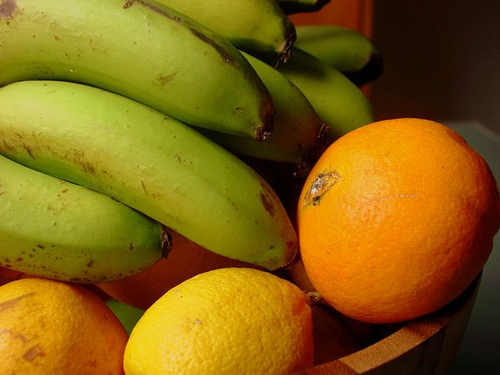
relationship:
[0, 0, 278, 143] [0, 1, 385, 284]
banana in bunch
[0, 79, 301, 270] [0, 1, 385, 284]
banana in bunch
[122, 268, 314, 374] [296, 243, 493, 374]
lemon in bowl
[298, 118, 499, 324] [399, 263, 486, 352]
orange resting on edge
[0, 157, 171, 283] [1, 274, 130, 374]
banana resting on orange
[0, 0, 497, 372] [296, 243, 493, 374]
fruit in bowl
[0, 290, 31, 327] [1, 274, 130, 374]
mark on orange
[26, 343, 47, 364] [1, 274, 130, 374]
mark on orange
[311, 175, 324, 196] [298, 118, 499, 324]
spot on orange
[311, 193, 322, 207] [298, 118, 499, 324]
spot on orange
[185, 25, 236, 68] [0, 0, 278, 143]
discoloration on banana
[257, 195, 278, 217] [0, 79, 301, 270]
discoloration on banana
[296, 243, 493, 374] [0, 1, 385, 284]
bowl holding bananas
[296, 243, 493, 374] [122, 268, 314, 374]
bowl holding lemon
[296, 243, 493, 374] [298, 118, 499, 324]
bowl holding orange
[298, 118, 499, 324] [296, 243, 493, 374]
orange in basket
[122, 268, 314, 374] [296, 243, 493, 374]
lemon in basket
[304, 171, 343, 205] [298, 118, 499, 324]
bruise on orange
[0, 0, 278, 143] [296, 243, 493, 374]
banana in basket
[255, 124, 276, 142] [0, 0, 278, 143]
stem on banana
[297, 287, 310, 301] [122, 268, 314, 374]
stem on lemon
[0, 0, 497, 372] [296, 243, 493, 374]
fruit in basket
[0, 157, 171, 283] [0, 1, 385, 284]
banana in bunch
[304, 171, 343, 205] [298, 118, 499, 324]
scar on orange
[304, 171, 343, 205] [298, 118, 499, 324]
spiderweb on orange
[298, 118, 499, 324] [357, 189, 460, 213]
orange has scratches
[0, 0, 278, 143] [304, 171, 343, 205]
banana has bruise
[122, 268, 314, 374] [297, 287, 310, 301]
citrus has stem